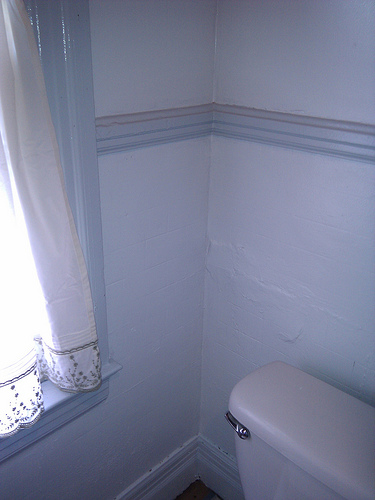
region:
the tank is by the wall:
[221, 358, 373, 496]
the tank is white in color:
[225, 354, 372, 497]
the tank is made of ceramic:
[227, 361, 374, 496]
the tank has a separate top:
[226, 358, 372, 497]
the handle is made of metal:
[224, 411, 250, 442]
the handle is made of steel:
[224, 408, 253, 444]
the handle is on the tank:
[223, 409, 252, 442]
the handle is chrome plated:
[222, 409, 251, 442]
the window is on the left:
[2, 199, 102, 434]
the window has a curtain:
[4, 197, 97, 433]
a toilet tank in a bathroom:
[2, 8, 373, 498]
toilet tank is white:
[220, 357, 373, 497]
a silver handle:
[218, 404, 253, 444]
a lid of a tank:
[225, 355, 372, 494]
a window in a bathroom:
[0, 7, 121, 446]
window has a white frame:
[1, 8, 122, 454]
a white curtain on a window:
[3, 10, 108, 438]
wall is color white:
[94, 12, 373, 368]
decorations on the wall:
[96, 100, 372, 167]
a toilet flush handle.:
[221, 407, 251, 439]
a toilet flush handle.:
[216, 405, 246, 435]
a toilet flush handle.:
[216, 405, 254, 442]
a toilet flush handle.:
[218, 405, 250, 443]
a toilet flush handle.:
[218, 401, 250, 440]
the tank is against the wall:
[227, 361, 372, 498]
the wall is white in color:
[202, 1, 373, 490]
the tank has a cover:
[229, 362, 368, 498]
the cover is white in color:
[231, 355, 371, 496]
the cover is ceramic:
[227, 354, 374, 497]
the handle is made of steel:
[225, 408, 249, 438]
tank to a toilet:
[207, 362, 367, 494]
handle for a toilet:
[222, 408, 252, 444]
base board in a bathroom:
[155, 432, 232, 492]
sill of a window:
[6, 351, 131, 464]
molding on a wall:
[97, 100, 369, 192]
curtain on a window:
[6, 229, 107, 430]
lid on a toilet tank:
[238, 363, 371, 478]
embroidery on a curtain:
[66, 350, 103, 390]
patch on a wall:
[201, 231, 297, 312]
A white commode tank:
[200, 364, 322, 473]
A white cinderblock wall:
[116, 318, 219, 421]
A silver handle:
[219, 401, 246, 454]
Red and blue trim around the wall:
[102, 97, 331, 184]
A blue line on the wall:
[254, 130, 317, 144]